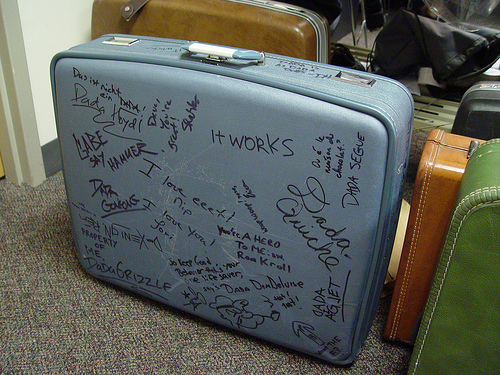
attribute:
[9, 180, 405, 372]
carpet — rough , gray 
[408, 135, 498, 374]
suitcase — green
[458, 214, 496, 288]
leather — green 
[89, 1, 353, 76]
suitcase — brown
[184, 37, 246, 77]
tag — white 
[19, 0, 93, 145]
wall — bright white, painted 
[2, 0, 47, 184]
door frame — gray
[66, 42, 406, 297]
suitcase — blue 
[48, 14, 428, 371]
suitcase — green, blue, black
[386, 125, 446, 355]
stitching — white, thick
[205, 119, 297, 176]
writing — black 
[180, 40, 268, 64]
handle — blue , white 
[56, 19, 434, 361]
bag — black , softcover 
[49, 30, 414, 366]
luggage — blue 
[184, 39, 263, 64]
handle — White , blue 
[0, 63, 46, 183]
frame — white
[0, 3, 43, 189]
door frame — wooden , white 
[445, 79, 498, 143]
luggage — metal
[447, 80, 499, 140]
black suitcase — black 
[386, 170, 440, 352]
stitching — White 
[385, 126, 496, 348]
luggage — brown 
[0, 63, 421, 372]
carpet — thin , blue 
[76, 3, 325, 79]
luggage — Brown , metal 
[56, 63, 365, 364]
signatures — black 